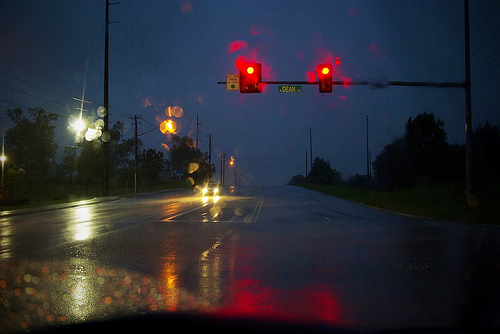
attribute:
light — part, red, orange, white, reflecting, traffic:
[241, 60, 262, 79]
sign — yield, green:
[211, 74, 243, 94]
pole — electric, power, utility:
[398, 73, 472, 97]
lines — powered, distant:
[102, 13, 120, 63]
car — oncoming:
[202, 182, 217, 186]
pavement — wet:
[53, 204, 94, 237]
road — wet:
[199, 224, 264, 254]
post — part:
[163, 141, 175, 183]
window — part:
[208, 183, 216, 187]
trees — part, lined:
[4, 127, 51, 171]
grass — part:
[35, 197, 63, 205]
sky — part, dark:
[351, 21, 381, 42]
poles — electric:
[61, 17, 125, 92]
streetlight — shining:
[150, 114, 170, 138]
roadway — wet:
[197, 196, 279, 248]